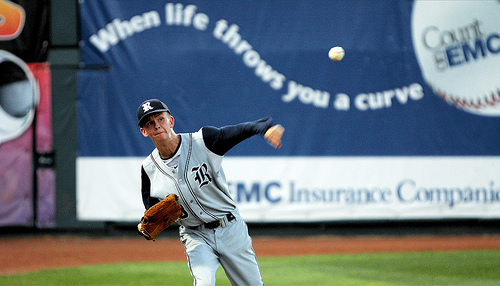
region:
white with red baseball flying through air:
[328, 45, 345, 62]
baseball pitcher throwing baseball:
[136, 100, 284, 284]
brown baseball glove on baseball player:
[138, 191, 183, 244]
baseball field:
[1, 237, 498, 284]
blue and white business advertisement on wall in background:
[77, 0, 497, 234]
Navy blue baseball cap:
[136, 99, 171, 125]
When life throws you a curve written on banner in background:
[88, 3, 427, 111]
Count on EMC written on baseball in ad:
[421, 19, 499, 68]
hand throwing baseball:
[263, 123, 285, 150]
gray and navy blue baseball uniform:
[140, 117, 267, 284]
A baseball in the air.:
[330, 46, 344, 60]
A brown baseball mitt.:
[142, 195, 183, 238]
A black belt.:
[187, 213, 234, 228]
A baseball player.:
[138, 98, 283, 284]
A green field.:
[1, 249, 498, 284]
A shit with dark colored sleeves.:
[141, 117, 275, 224]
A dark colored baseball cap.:
[137, 98, 169, 125]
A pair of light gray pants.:
[181, 210, 263, 284]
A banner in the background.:
[75, 1, 499, 219]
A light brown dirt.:
[0, 233, 497, 272]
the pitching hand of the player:
[264, 123, 289, 156]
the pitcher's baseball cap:
[132, 99, 180, 119]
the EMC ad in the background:
[83, 5, 499, 136]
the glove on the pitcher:
[138, 197, 190, 235]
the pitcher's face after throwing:
[141, 118, 181, 160]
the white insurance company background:
[81, 158, 494, 210]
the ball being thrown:
[313, 36, 349, 69]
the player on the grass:
[134, 100, 279, 280]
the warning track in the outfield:
[1, 236, 497, 284]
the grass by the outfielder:
[16, 261, 466, 284]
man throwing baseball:
[122, 94, 284, 283]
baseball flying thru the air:
[326, 44, 345, 61]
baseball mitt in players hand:
[136, 191, 186, 243]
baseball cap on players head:
[131, 94, 169, 124]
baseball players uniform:
[132, 117, 274, 284]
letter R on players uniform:
[189, 159, 216, 193]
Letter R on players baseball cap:
[140, 99, 153, 114]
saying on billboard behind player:
[82, 0, 425, 119]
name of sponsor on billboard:
[229, 176, 498, 220]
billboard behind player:
[76, 2, 497, 227]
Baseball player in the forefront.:
[132, 94, 274, 281]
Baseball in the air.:
[326, 45, 346, 61]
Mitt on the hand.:
[136, 190, 186, 242]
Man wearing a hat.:
[134, 91, 181, 146]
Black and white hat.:
[130, 97, 174, 124]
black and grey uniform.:
[130, 93, 272, 284]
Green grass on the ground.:
[1, 250, 496, 285]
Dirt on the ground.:
[0, 231, 499, 281]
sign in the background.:
[74, 5, 496, 227]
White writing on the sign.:
[87, 3, 427, 113]